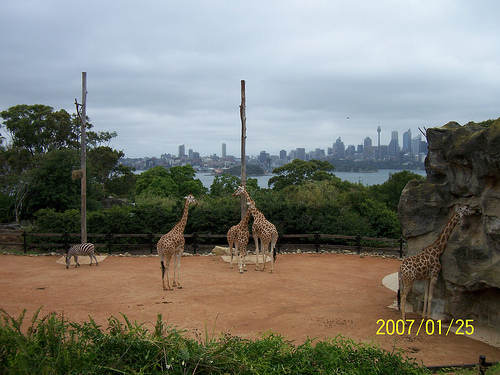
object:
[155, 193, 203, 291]
giraffes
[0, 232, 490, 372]
enclosure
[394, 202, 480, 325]
giraffe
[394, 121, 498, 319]
rock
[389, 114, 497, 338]
face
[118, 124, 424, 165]
skyline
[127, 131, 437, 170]
city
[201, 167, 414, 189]
water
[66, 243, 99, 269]
zebra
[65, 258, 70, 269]
face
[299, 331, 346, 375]
vegetation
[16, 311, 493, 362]
foreground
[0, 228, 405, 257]
fence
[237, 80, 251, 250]
pole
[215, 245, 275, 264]
food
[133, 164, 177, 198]
trees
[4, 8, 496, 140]
sky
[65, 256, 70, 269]
head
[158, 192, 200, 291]
animals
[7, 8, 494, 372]
habitat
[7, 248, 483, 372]
area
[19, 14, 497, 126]
smog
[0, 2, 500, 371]
air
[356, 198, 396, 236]
shrub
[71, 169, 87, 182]
hay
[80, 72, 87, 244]
rope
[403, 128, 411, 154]
skyscrapers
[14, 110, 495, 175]
horizon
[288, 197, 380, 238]
bushes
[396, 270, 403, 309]
tail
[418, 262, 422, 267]
spots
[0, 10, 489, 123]
clouds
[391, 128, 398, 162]
buildings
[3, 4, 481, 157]
background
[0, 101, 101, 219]
plants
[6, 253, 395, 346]
sand